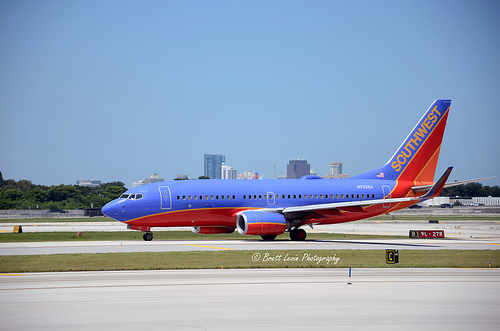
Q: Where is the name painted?
A: On the plane tail.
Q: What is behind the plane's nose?
A: Trees.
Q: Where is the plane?
A: On the runway.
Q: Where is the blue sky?
A: Above the airplane.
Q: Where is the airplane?
A: On the runway.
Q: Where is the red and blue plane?
A: On the runway.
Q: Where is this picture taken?
A: Air strip.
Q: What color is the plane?
A: Blue and red.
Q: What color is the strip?
A: Gray.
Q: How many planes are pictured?
A: One.